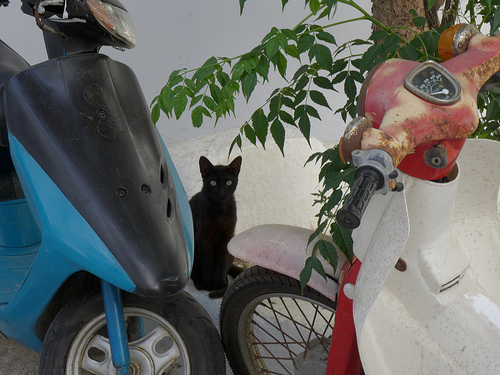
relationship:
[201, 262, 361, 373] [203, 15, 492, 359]
wheel on motorbike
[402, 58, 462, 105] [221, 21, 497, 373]
gauge on top of scooter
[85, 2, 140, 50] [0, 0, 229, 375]
light on front of moped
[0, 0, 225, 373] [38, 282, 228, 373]
moped has wheel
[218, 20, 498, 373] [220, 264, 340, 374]
moped has wheel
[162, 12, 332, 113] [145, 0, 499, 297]
leaves hanging from plant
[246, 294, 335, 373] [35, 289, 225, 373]
spokes in tire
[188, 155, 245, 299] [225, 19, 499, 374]
cat between mopeds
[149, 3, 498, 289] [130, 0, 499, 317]
green foliage of a tree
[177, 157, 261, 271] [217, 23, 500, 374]
cat next to moped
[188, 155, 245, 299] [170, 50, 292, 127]
cat sitting underneath plant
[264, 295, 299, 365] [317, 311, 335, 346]
spoke on spoke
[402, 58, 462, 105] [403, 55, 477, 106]
gauge on moped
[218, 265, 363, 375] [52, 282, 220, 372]
wheel on moped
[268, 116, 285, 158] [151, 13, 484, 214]
green foliage on tree